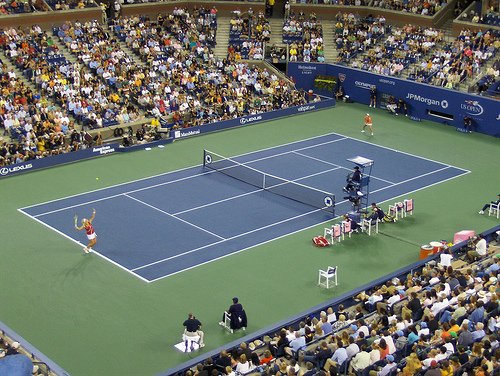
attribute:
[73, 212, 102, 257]
player — crouched, stretching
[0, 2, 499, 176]
audience — big, full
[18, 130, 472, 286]
court — blue, green, long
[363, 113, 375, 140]
player — opponent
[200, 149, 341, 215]
net — black, white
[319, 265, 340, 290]
chair — white, empty